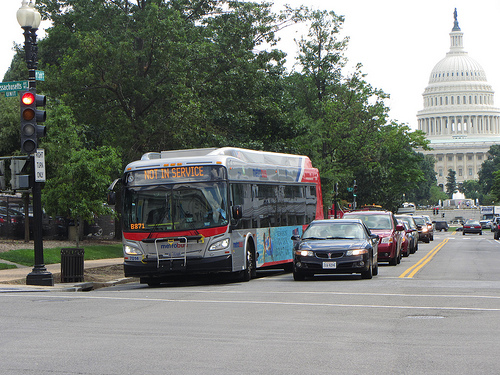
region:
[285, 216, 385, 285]
car on a street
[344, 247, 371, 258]
headlight on a vehicle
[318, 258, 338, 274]
front licence plate on a vehicle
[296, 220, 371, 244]
front window on a vehicle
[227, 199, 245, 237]
side rear view mirror on a vehicle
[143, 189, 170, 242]
windshield wiper on a vehicle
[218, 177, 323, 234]
side windows on a bus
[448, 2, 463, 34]
statue on top of a domed building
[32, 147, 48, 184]
black and white sign on a pole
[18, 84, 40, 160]
traffic signal on a pole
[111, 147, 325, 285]
bus stopped at red light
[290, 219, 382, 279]
car stopped at red light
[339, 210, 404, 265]
car stopped at red light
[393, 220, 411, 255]
car stopped at red light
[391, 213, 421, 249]
car stopped at red light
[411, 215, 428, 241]
car stopped at red light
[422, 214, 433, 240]
car stopped at red light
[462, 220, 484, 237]
car driving on road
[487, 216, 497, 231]
car stopped at red light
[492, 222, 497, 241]
car stopped at red light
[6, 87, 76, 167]
the light is red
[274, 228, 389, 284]
the headlights are on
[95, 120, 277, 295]
a bus in traffic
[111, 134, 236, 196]
the bus is not in service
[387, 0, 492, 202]
the washington monument in the background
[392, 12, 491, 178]
the building is white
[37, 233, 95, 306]
a garbage can on the corner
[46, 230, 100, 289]
the garbage can is black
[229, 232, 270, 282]
the wheel is black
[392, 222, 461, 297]
two lines in the street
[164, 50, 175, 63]
leaves on the tree.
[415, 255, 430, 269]
yellow lines on the road.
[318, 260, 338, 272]
license plate on vehicle.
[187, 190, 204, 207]
windshield on the bus.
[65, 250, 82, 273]
trash can on sidewalk.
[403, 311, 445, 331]
manhole on the road.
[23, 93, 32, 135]
traffic lights on pole.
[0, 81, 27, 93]
street sign on pole.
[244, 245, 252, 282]
tire on the bus.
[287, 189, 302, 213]
window on the bus.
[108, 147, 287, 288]
The bus is stopped on the street.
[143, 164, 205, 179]
The words not in service are on the bus.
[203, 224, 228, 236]
The bus is red.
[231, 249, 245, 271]
The bus is silver.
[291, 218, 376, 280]
A car is next to the bus.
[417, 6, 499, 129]
The Capitol building is in the background.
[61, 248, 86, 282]
A trash can is on the sidewalk.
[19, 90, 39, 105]
The traffic light is red.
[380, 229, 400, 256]
The vehicle is red.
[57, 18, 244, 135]
Trees line the street.